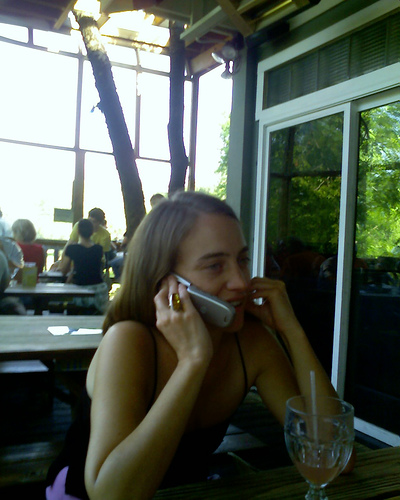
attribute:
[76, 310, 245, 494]
tank top — black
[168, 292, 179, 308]
ring — gold, large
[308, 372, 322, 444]
straw — white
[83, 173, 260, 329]
hair — long, straight, brown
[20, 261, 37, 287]
container — yellow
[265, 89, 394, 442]
door — glass, sliding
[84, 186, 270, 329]
girl — brown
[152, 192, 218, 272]
hair — long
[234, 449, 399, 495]
table — wood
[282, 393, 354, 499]
cup — glass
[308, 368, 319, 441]
straw — white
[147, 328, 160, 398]
straps — spaghetti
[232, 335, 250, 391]
straps — spaghetti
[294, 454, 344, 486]
liquid — yellow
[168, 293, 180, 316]
stone — yellow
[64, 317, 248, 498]
shirt — black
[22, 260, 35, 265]
top — white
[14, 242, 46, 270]
shirt — red